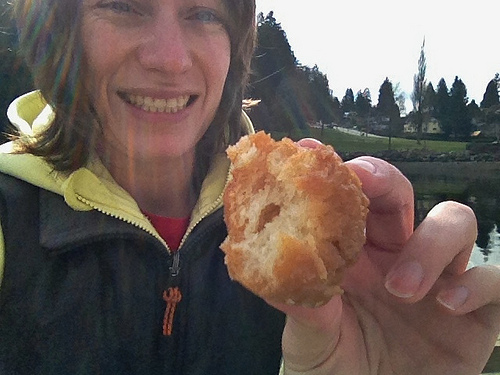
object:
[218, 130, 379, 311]
cake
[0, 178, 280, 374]
jacket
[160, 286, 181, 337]
rope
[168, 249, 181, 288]
zipper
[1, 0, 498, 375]
lady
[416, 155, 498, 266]
water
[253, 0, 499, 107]
sky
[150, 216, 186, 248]
shirt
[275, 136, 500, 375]
hand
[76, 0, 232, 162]
face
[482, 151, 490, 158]
rocks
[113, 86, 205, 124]
smile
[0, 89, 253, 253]
insert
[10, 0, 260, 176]
hair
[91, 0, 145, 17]
eye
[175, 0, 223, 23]
eye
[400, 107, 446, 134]
house